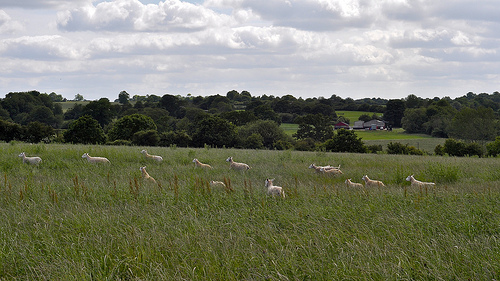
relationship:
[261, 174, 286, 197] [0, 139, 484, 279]
sheep standing in field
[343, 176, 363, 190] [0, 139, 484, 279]
sheep standing in field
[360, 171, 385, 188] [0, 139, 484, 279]
sheep standing in field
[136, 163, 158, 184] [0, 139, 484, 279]
sheep standing in field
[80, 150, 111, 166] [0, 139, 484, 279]
sheep standing in field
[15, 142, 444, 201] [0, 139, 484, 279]
sheep in a field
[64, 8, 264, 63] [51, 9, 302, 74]
clouds in sky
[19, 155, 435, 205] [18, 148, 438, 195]
sheep in grass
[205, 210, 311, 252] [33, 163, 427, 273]
grass of a field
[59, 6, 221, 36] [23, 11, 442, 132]
clouds in sky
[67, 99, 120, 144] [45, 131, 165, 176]
tree beyond grass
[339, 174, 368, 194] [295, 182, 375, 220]
sheep in grass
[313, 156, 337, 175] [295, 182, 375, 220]
sheep in grass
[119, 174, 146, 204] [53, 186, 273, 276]
weeds in grass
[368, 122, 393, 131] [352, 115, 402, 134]
cars parked near a barn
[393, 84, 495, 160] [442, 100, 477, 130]
trees with leaves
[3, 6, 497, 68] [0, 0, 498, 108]
clouds in sky